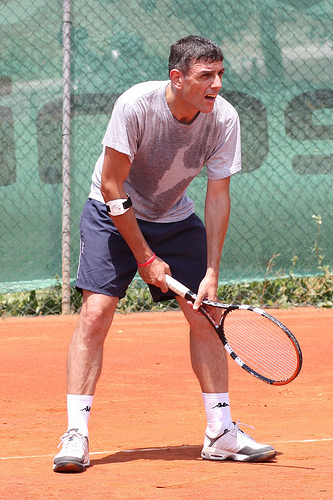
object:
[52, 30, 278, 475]
tennis player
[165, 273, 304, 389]
tennis racket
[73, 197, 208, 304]
shorts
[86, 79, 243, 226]
t-shirt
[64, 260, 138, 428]
leg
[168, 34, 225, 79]
hair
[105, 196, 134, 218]
wrist band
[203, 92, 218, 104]
mouth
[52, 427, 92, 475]
shoe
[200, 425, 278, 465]
shoe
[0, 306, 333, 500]
court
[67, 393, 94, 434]
sock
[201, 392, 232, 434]
sock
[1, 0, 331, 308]
fence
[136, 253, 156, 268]
arm band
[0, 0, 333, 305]
background court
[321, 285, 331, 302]
plants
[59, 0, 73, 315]
fence post